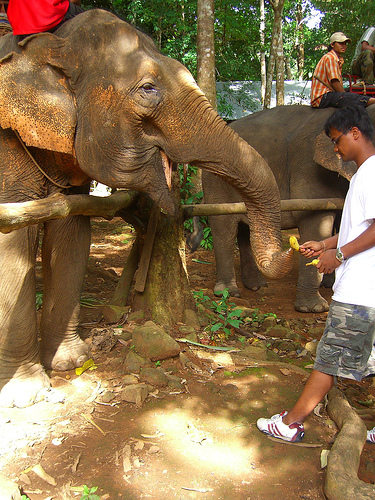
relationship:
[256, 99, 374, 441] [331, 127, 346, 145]
boy wearing eyeglasses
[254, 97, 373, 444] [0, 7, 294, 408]
man feeding elephant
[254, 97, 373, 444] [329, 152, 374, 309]
man wearing shirt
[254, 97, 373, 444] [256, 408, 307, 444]
man wearing shoe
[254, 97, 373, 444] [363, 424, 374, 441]
man wearing shoe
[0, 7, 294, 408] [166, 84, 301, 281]
elephant has trunk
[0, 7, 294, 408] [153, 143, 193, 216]
elephant has mouth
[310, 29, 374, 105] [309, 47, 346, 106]
man wearing shirt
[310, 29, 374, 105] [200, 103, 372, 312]
man sitting on elephant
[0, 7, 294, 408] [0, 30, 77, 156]
elephant has ear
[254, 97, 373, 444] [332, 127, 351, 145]
man wearing eyeglasses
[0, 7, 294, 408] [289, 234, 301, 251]
elephant eating banana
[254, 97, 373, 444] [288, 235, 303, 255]
man holding banana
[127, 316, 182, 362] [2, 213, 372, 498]
rock on ground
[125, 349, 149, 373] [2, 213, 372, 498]
rock on ground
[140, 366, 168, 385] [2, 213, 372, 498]
rock on ground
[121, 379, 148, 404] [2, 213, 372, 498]
rock on ground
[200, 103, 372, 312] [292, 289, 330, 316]
elephant has foot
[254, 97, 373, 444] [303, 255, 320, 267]
man holding banana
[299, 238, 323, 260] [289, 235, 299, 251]
hand holding banana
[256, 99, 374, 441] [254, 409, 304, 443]
boy wearing shoe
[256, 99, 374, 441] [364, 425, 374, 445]
boy wearing shoe